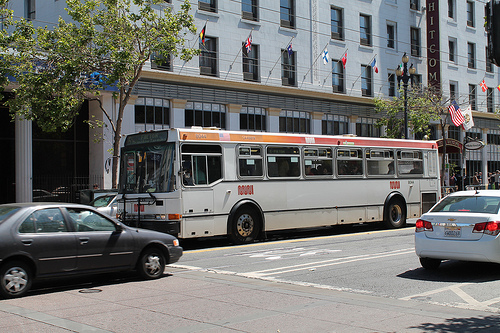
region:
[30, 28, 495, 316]
cars and bus on a a road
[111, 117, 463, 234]
long white and red bus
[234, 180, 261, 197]
red numbers on side of bus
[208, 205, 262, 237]
black wheel on bottom of bus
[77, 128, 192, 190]
front window on bus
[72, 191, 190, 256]
grey car by bus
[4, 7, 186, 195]
skinny tree standing up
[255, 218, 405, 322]
asphalt road on ground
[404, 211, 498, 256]
tail ends of a car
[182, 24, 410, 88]
flags hanging from building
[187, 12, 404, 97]
plenty flags are visible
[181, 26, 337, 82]
plenty flags are visible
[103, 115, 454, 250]
a bus is white and orange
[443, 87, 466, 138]
an American flag on a building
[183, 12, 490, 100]
several flags on a second floor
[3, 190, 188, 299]
a car in the street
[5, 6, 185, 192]
a tree in front of a building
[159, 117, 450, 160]
a stripe orange on top of building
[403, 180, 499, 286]
a white car on right of street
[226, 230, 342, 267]
letter STOP on the road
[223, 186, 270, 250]
front wheel of bus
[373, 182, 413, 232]
back wheel of car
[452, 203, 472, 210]
a red brake light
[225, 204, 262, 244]
the tire of a bus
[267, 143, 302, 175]
the window of a bus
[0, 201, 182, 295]
a small gray car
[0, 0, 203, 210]
a tall green tree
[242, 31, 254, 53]
a red, white and blue flag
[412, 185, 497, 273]
a white car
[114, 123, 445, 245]
a long white bus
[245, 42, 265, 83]
a long window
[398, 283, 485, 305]
a white street marking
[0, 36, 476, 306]
white and red bus parked onn road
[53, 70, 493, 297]
cars and a bus on the road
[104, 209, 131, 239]
side view mirror on car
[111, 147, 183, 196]
front windshield on bus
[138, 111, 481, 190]
side windshields on bus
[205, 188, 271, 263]
front wheel on bus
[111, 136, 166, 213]
windshield wipers on bus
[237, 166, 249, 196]
red numbers on bus side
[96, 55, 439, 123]
flags on building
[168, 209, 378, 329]
white paint marks on the street